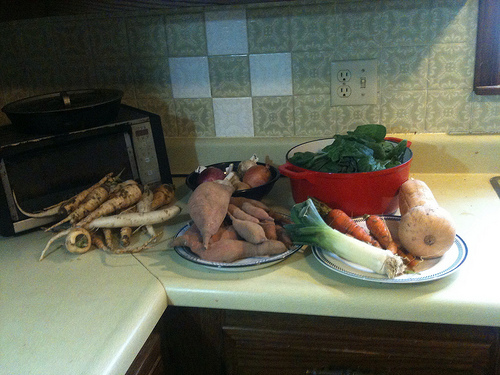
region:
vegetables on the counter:
[41, 131, 473, 285]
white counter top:
[16, 259, 141, 361]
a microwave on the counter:
[11, 105, 170, 233]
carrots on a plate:
[321, 200, 388, 238]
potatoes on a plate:
[182, 175, 277, 260]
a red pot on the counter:
[280, 145, 420, 210]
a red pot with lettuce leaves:
[285, 127, 411, 217]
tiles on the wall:
[160, 11, 316, 131]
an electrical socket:
[335, 55, 358, 100]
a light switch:
[356, 60, 375, 110]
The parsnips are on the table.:
[11, 173, 182, 264]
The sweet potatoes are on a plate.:
[169, 176, 298, 267]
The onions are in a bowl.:
[188, 156, 278, 193]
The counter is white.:
[12, 277, 95, 342]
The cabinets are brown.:
[225, 319, 342, 363]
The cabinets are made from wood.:
[226, 318, 339, 368]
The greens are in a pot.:
[281, 123, 421, 210]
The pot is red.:
[281, 121, 418, 214]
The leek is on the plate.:
[291, 201, 406, 271]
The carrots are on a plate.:
[311, 199, 405, 264]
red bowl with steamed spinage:
[281, 121, 418, 224]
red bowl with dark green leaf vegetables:
[281, 117, 418, 210]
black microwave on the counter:
[0, 95, 170, 235]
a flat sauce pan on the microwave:
[3, 82, 125, 132]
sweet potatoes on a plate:
[170, 196, 313, 268]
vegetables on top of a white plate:
[286, 177, 465, 290]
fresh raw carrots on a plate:
[318, 205, 415, 269]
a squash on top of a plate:
[393, 173, 455, 262]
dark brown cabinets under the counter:
[168, 308, 498, 369]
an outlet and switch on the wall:
[327, 61, 380, 108]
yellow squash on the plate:
[397, 175, 459, 254]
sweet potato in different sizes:
[176, 188, 285, 260]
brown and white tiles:
[127, 8, 305, 96]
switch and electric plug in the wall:
[328, 51, 383, 114]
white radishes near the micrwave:
[63, 179, 170, 245]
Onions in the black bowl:
[183, 157, 279, 192]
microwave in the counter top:
[4, 85, 176, 239]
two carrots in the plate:
[327, 205, 397, 245]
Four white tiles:
[164, 6, 292, 138]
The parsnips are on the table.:
[11, 172, 181, 257]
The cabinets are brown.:
[221, 318, 293, 361]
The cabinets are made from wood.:
[228, 335, 333, 369]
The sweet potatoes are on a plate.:
[170, 168, 297, 268]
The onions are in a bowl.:
[184, 151, 281, 196]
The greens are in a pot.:
[276, 115, 418, 211]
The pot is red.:
[281, 119, 421, 219]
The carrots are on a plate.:
[329, 206, 415, 262]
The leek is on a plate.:
[278, 197, 403, 277]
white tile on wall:
[213, 95, 255, 138]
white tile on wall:
[250, 50, 295, 99]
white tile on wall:
[204, 10, 246, 64]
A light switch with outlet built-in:
[322, 43, 382, 119]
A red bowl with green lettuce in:
[289, 111, 438, 223]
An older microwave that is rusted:
[11, 104, 165, 251]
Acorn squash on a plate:
[368, 160, 455, 267]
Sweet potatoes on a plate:
[157, 180, 270, 280]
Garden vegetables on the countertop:
[48, 120, 462, 309]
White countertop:
[19, 263, 114, 372]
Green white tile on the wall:
[395, 89, 446, 145]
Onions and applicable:
[171, 136, 281, 227]